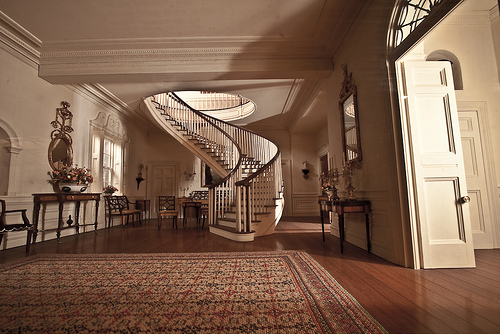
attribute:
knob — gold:
[455, 188, 473, 208]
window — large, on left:
[88, 125, 128, 191]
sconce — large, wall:
[288, 142, 340, 207]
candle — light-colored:
[295, 157, 312, 173]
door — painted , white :
[404, 51, 490, 276]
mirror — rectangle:
[336, 68, 365, 168]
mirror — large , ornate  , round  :
[35, 113, 87, 190]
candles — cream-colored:
[314, 161, 339, 177]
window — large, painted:
[94, 138, 120, 193]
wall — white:
[1, 31, 147, 251]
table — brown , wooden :
[26, 188, 115, 240]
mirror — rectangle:
[339, 77, 366, 166]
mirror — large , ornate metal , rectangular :
[327, 62, 375, 175]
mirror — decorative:
[23, 102, 102, 194]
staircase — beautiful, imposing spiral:
[121, 53, 301, 247]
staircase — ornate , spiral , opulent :
[156, 91, 278, 231]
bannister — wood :
[183, 95, 280, 185]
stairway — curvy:
[139, 88, 289, 243]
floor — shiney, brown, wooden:
[1, 217, 499, 332]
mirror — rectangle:
[328, 65, 372, 167]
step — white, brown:
[207, 222, 255, 240]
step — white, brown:
[217, 215, 244, 229]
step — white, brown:
[222, 208, 267, 220]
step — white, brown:
[230, 202, 278, 210]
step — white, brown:
[231, 197, 281, 205]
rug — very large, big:
[0, 245, 389, 332]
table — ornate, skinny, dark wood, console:
[34, 190, 102, 235]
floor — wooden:
[348, 273, 494, 332]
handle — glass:
[458, 191, 469, 206]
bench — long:
[103, 186, 132, 221]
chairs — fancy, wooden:
[103, 191, 141, 223]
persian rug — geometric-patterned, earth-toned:
[5, 249, 385, 332]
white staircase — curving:
[151, 91, 287, 239]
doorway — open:
[385, 9, 498, 271]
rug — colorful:
[78, 240, 287, 314]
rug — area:
[3, 255, 393, 330]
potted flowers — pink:
[53, 164, 93, 184]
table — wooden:
[33, 186, 110, 218]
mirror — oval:
[49, 135, 71, 174]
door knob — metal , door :
[451, 188, 477, 209]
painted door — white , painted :
[379, 54, 478, 269]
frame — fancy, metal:
[46, 99, 74, 172]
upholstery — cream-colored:
[104, 207, 142, 221]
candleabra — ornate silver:
[316, 165, 339, 200]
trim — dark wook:
[168, 94, 282, 194]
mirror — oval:
[47, 127, 74, 173]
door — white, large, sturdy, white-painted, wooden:
[397, 55, 478, 276]